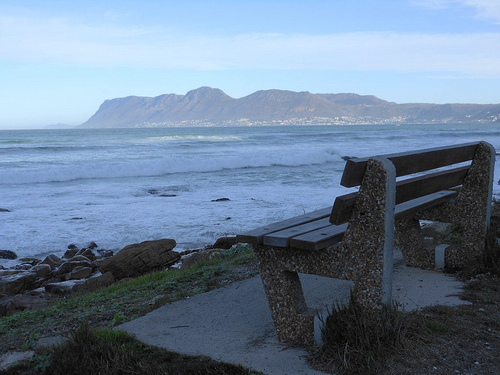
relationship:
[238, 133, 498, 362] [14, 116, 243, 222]
bench by water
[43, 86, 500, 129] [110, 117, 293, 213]
mountains on side of water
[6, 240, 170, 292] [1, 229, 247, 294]
rocks near beach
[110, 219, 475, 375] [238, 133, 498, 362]
concete beneath bench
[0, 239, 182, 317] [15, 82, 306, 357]
rocks at shore line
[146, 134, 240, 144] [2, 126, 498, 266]
cap on water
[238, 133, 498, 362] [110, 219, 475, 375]
bench on concete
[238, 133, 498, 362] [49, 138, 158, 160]
bench overlooks water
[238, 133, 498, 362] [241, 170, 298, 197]
bench overlooks water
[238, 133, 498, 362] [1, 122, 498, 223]
bench overlooks water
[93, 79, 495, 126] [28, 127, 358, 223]
mountains sit alongs water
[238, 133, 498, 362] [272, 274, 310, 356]
bench made of rocks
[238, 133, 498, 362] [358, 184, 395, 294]
bench made of wood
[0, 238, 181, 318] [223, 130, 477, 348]
clump next to bench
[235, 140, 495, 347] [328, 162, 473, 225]
bench has slat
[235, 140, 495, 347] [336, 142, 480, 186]
bench has slat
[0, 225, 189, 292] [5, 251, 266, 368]
clump against ground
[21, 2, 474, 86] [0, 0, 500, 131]
blue sky with blue sky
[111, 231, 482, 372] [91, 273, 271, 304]
concete in grass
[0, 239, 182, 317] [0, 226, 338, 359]
rocks along shore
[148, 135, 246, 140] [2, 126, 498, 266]
cap in water